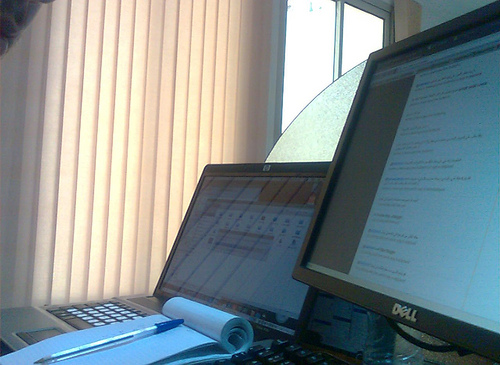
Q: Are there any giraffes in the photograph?
A: No, there are no giraffes.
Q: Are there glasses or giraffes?
A: No, there are no giraffes or glasses.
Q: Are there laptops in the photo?
A: Yes, there is a laptop.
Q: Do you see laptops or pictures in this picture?
A: Yes, there is a laptop.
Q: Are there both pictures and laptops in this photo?
A: No, there is a laptop but no pictures.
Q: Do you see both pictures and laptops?
A: No, there is a laptop but no pictures.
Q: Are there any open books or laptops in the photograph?
A: Yes, there is an open laptop.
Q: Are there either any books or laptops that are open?
A: Yes, the laptop is open.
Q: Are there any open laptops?
A: Yes, there is an open laptop.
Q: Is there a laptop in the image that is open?
A: Yes, there is a laptop that is open.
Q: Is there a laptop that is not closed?
A: Yes, there is a open laptop.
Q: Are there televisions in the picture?
A: No, there are no televisions.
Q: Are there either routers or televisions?
A: No, there are no televisions or routers.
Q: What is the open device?
A: The device is a laptop.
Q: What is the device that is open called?
A: The device is a laptop.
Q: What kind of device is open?
A: The device is a laptop.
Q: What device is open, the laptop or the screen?
A: The laptop is open.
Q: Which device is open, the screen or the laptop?
A: The laptop is open.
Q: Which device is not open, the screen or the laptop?
A: The screen is not open.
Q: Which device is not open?
A: The device is a screen.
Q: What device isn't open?
A: The device is a screen.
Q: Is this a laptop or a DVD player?
A: This is a laptop.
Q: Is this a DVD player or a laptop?
A: This is a laptop.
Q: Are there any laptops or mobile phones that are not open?
A: No, there is a laptop but it is open.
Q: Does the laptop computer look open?
A: Yes, the laptop computer is open.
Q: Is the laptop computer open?
A: Yes, the laptop computer is open.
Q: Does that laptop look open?
A: Yes, the laptop is open.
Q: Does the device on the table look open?
A: Yes, the laptop is open.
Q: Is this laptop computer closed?
A: No, the laptop computer is open.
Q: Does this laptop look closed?
A: No, the laptop is open.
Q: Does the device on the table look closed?
A: No, the laptop is open.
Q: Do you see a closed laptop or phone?
A: No, there is a laptop but it is open.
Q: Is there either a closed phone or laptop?
A: No, there is a laptop but it is open.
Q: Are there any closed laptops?
A: No, there is a laptop but it is open.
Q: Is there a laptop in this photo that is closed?
A: No, there is a laptop but it is open.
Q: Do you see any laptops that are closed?
A: No, there is a laptop but it is open.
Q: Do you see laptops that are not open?
A: No, there is a laptop but it is open.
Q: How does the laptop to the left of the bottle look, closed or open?
A: The laptop is open.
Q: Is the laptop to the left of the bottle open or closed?
A: The laptop is open.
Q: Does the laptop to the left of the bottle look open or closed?
A: The laptop is open.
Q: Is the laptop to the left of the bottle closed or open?
A: The laptop is open.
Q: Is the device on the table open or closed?
A: The laptop is open.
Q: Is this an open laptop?
A: Yes, this is an open laptop.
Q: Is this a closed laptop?
A: No, this is an open laptop.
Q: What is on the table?
A: The laptop is on the table.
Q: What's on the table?
A: The laptop is on the table.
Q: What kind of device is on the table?
A: The device is a laptop.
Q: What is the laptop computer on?
A: The laptop computer is on the table.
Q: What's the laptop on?
A: The laptop computer is on the table.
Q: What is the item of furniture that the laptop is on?
A: The piece of furniture is a table.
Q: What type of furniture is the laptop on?
A: The laptop is on the table.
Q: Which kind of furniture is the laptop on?
A: The laptop is on the table.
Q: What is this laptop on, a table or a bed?
A: The laptop is on a table.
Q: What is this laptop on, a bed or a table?
A: The laptop is on a table.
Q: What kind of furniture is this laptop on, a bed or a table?
A: The laptop is on a table.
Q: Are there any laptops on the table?
A: Yes, there is a laptop on the table.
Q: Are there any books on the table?
A: No, there is a laptop on the table.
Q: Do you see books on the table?
A: No, there is a laptop on the table.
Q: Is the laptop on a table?
A: Yes, the laptop is on a table.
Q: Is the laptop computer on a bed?
A: No, the laptop computer is on a table.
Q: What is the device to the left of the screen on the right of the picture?
A: The device is a laptop.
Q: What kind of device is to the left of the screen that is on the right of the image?
A: The device is a laptop.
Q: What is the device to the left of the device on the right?
A: The device is a laptop.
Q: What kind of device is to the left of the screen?
A: The device is a laptop.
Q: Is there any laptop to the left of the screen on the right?
A: Yes, there is a laptop to the left of the screen.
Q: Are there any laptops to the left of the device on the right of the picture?
A: Yes, there is a laptop to the left of the screen.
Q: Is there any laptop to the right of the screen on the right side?
A: No, the laptop is to the left of the screen.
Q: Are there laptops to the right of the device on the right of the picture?
A: No, the laptop is to the left of the screen.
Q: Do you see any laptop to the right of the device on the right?
A: No, the laptop is to the left of the screen.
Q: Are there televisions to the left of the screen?
A: No, there is a laptop to the left of the screen.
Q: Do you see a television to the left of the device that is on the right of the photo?
A: No, there is a laptop to the left of the screen.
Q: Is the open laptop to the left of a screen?
A: Yes, the laptop is to the left of a screen.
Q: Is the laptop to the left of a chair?
A: No, the laptop is to the left of a screen.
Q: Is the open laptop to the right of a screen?
A: No, the laptop is to the left of a screen.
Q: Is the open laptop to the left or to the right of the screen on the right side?
A: The laptop is to the left of the screen.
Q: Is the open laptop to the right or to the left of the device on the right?
A: The laptop is to the left of the screen.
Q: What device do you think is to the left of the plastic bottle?
A: The device is a laptop.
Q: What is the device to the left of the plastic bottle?
A: The device is a laptop.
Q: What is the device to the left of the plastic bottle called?
A: The device is a laptop.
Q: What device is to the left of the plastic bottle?
A: The device is a laptop.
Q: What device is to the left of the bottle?
A: The device is a laptop.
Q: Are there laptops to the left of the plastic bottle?
A: Yes, there is a laptop to the left of the bottle.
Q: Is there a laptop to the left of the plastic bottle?
A: Yes, there is a laptop to the left of the bottle.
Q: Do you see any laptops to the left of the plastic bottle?
A: Yes, there is a laptop to the left of the bottle.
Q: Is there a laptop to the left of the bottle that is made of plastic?
A: Yes, there is a laptop to the left of the bottle.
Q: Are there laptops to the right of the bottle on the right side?
A: No, the laptop is to the left of the bottle.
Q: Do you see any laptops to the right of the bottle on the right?
A: No, the laptop is to the left of the bottle.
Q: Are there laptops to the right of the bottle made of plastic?
A: No, the laptop is to the left of the bottle.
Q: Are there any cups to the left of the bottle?
A: No, there is a laptop to the left of the bottle.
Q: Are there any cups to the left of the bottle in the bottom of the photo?
A: No, there is a laptop to the left of the bottle.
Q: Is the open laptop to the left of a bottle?
A: Yes, the laptop is to the left of a bottle.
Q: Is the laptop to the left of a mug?
A: No, the laptop is to the left of a bottle.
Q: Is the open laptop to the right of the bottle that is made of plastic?
A: No, the laptop computer is to the left of the bottle.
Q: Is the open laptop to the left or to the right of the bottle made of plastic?
A: The laptop computer is to the left of the bottle.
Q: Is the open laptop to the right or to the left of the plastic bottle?
A: The laptop computer is to the left of the bottle.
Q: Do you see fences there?
A: No, there are no fences.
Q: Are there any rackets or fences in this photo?
A: No, there are no fences or rackets.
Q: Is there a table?
A: Yes, there is a table.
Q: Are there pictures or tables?
A: Yes, there is a table.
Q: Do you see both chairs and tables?
A: No, there is a table but no chairs.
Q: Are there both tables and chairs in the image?
A: No, there is a table but no chairs.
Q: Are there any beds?
A: No, there are no beds.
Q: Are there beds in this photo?
A: No, there are no beds.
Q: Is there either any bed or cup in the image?
A: No, there are no beds or cups.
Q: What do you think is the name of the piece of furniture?
A: The piece of furniture is a table.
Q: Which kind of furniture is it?
A: The piece of furniture is a table.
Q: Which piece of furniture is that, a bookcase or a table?
A: This is a table.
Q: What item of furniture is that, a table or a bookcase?
A: This is a table.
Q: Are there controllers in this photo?
A: No, there are no controllers.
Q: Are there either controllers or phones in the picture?
A: No, there are no controllers or phones.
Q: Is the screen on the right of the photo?
A: Yes, the screen is on the right of the image.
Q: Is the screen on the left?
A: No, the screen is on the right of the image.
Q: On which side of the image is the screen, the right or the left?
A: The screen is on the right of the image.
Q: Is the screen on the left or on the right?
A: The screen is on the right of the image.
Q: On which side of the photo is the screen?
A: The screen is on the right of the image.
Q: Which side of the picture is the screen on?
A: The screen is on the right of the image.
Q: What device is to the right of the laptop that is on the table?
A: The device is a screen.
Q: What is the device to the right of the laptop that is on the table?
A: The device is a screen.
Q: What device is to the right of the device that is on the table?
A: The device is a screen.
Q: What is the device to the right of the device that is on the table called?
A: The device is a screen.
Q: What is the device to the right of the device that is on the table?
A: The device is a screen.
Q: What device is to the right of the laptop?
A: The device is a screen.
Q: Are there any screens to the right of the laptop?
A: Yes, there is a screen to the right of the laptop.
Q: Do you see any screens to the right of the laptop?
A: Yes, there is a screen to the right of the laptop.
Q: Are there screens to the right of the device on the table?
A: Yes, there is a screen to the right of the laptop.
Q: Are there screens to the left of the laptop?
A: No, the screen is to the right of the laptop.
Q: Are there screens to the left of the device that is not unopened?
A: No, the screen is to the right of the laptop.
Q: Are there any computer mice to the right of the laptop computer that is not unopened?
A: No, there is a screen to the right of the laptop.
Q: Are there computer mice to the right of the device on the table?
A: No, there is a screen to the right of the laptop.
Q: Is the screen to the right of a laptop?
A: Yes, the screen is to the right of a laptop.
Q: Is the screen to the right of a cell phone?
A: No, the screen is to the right of a laptop.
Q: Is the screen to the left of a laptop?
A: No, the screen is to the right of a laptop.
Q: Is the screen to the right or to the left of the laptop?
A: The screen is to the right of the laptop.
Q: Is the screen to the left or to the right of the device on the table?
A: The screen is to the right of the laptop.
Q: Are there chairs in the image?
A: No, there are no chairs.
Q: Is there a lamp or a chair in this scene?
A: No, there are no chairs or lamps.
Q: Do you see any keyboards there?
A: Yes, there is a keyboard.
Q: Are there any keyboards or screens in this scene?
A: Yes, there is a keyboard.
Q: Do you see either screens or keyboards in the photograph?
A: Yes, there is a keyboard.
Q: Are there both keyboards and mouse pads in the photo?
A: No, there is a keyboard but no mouse pads.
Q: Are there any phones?
A: No, there are no phones.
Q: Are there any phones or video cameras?
A: No, there are no phones or video cameras.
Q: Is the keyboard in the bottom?
A: Yes, the keyboard is in the bottom of the image.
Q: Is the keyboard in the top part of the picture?
A: No, the keyboard is in the bottom of the image.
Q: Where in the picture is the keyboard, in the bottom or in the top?
A: The keyboard is in the bottom of the image.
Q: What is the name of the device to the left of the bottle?
A: The device is a keyboard.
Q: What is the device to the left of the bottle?
A: The device is a keyboard.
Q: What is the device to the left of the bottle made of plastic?
A: The device is a keyboard.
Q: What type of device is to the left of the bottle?
A: The device is a keyboard.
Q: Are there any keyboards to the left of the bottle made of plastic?
A: Yes, there is a keyboard to the left of the bottle.